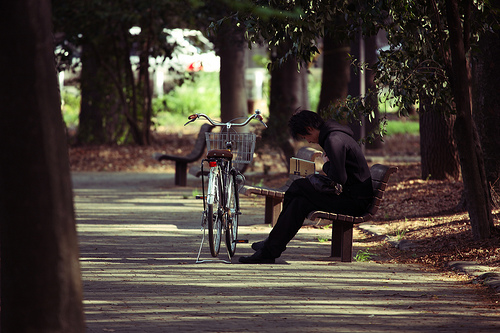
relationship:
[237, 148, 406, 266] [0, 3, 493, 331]
bench in park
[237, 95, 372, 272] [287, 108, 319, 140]
person has head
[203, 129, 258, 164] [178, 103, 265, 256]
basket on bike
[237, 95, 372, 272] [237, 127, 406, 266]
person sitting on bench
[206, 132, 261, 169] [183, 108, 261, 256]
basket front of bike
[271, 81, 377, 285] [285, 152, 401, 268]
man sits on bench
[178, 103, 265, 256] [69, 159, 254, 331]
bike on walkway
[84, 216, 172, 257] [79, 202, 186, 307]
sunlight on ground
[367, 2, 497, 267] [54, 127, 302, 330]
tree over path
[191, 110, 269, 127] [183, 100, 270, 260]
handle of bike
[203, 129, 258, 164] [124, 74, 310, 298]
basket on front of bike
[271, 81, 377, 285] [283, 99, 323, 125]
man has short hair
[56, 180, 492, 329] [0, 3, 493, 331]
bike path though park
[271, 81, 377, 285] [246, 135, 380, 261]
man wears clothes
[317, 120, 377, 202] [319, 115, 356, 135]
sweatshirt has hood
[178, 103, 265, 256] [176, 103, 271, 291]
bike on ground